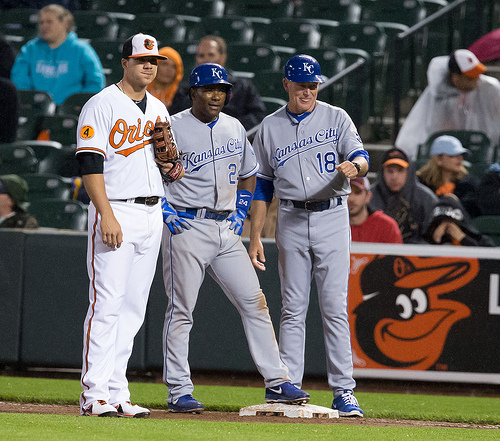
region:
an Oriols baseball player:
[72, 35, 171, 422]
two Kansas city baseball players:
[154, 52, 364, 421]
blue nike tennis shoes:
[170, 385, 372, 416]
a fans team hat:
[374, 145, 417, 168]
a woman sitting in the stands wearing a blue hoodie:
[13, 2, 104, 101]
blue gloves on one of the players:
[226, 180, 255, 238]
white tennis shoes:
[71, 389, 152, 424]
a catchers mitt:
[151, 116, 181, 170]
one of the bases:
[227, 392, 352, 437]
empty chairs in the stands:
[121, 1, 428, 78]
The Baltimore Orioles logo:
[365, 250, 456, 381]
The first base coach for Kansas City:
[250, 42, 365, 382]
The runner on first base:
[177, 31, 272, 356]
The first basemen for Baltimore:
[65, 36, 176, 387]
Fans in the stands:
[356, 57, 476, 228]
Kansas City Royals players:
[180, 37, 407, 392]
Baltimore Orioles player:
[56, 30, 191, 351]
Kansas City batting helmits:
[190, 50, 335, 90]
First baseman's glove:
[140, 110, 195, 176]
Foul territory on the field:
[30, 375, 476, 391]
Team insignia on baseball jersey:
[268, 126, 340, 163]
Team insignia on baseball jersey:
[111, 108, 173, 155]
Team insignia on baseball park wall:
[354, 256, 469, 366]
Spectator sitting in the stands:
[379, 147, 435, 239]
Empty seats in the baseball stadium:
[263, 13, 388, 62]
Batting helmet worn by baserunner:
[190, 60, 237, 114]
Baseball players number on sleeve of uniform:
[77, 119, 101, 144]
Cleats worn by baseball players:
[162, 387, 212, 418]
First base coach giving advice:
[260, 48, 373, 238]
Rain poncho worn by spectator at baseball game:
[394, 53, 499, 170]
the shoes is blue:
[252, 362, 367, 439]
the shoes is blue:
[253, 374, 308, 406]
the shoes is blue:
[243, 374, 338, 428]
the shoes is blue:
[273, 365, 318, 419]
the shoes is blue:
[239, 345, 316, 407]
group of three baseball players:
[71, 20, 387, 430]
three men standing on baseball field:
[52, 26, 422, 426]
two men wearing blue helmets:
[166, 51, 371, 416]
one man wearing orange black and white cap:
[69, 20, 184, 422]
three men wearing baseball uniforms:
[66, 13, 396, 422]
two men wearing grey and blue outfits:
[162, 62, 374, 419]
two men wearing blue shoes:
[164, 56, 374, 426]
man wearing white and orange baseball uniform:
[72, 28, 192, 420]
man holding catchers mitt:
[69, 31, 184, 422]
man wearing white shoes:
[78, 21, 185, 417]